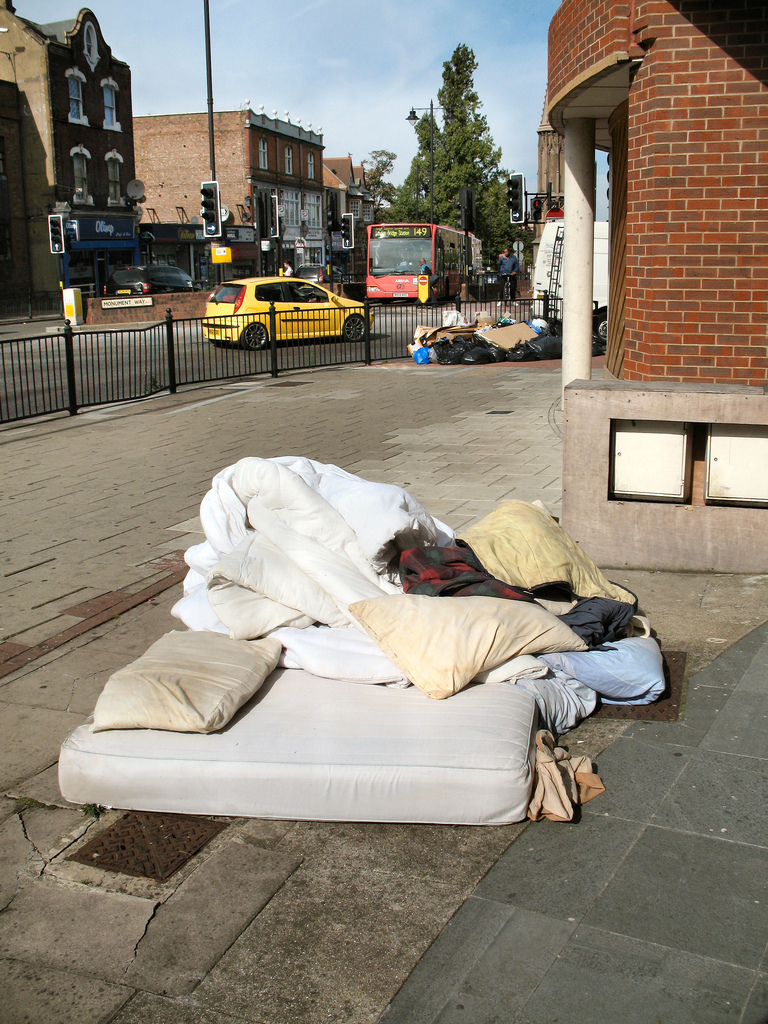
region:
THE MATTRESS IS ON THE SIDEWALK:
[39, 570, 620, 847]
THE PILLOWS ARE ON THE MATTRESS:
[80, 585, 591, 758]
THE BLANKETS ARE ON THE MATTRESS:
[162, 427, 656, 730]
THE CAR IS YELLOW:
[193, 265, 378, 353]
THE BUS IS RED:
[344, 208, 497, 314]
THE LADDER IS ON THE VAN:
[539, 224, 568, 324]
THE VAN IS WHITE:
[509, 177, 628, 356]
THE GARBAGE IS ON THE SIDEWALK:
[397, 303, 590, 385]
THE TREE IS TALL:
[368, 32, 527, 307]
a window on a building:
[65, 52, 86, 128]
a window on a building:
[75, 16, 102, 68]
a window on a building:
[61, 134, 92, 204]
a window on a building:
[258, 134, 272, 175]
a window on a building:
[302, 150, 323, 184]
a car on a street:
[209, 268, 370, 341]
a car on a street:
[136, 261, 194, 288]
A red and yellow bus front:
[359, 222, 442, 303]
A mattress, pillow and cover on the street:
[62, 453, 664, 826]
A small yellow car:
[199, 274, 374, 339]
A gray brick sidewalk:
[19, 869, 760, 1022]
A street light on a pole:
[189, 3, 225, 238]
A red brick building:
[557, 5, 766, 379]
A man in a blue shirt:
[497, 247, 521, 296]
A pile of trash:
[410, 302, 572, 364]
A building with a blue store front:
[53, 11, 134, 297]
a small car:
[181, 253, 385, 356]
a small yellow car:
[201, 265, 379, 367]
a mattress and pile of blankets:
[29, 448, 681, 852]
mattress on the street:
[33, 440, 690, 861]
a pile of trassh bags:
[398, 285, 561, 384]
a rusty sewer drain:
[52, 812, 220, 885]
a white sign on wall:
[102, 291, 155, 311]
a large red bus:
[364, 213, 491, 312]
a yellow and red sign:
[411, 269, 439, 306]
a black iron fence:
[0, 303, 428, 414]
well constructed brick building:
[548, 2, 766, 386]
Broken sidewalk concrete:
[2, 792, 191, 994]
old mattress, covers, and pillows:
[57, 452, 665, 823]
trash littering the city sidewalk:
[61, 454, 664, 825]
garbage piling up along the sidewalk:
[404, 316, 564, 363]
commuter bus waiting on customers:
[367, 221, 484, 305]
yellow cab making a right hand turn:
[198, 277, 374, 349]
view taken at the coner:
[2, 2, 756, 1021]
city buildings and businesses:
[1, 1, 372, 291]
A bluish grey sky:
[17, 4, 560, 194]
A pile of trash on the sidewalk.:
[398, 301, 600, 370]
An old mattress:
[71, 637, 574, 850]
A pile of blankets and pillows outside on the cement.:
[87, 458, 703, 718]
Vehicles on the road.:
[94, 202, 518, 366]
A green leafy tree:
[398, 38, 523, 282]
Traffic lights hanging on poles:
[31, 166, 226, 259]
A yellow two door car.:
[199, 255, 386, 343]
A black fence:
[0, 295, 583, 416]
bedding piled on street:
[157, 433, 617, 827]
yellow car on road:
[217, 264, 353, 367]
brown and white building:
[15, 10, 137, 268]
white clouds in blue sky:
[129, 25, 177, 79]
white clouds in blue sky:
[153, 47, 183, 88]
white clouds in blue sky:
[247, 23, 290, 69]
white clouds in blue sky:
[302, 19, 341, 54]